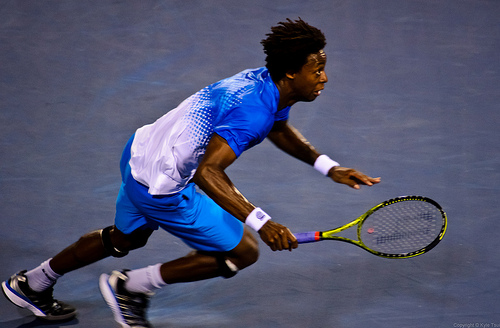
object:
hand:
[257, 220, 297, 251]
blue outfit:
[127, 66, 290, 192]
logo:
[376, 213, 430, 243]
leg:
[125, 184, 259, 281]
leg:
[50, 184, 154, 274]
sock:
[123, 262, 169, 291]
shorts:
[115, 134, 242, 251]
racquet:
[289, 195, 448, 256]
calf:
[50, 229, 129, 272]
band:
[215, 258, 237, 280]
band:
[99, 225, 126, 256]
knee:
[204, 227, 259, 271]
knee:
[111, 216, 147, 251]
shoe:
[1, 269, 77, 321]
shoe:
[97, 267, 154, 327]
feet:
[2, 269, 76, 320]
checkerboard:
[180, 66, 279, 158]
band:
[245, 207, 272, 232]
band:
[313, 154, 340, 176]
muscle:
[196, 165, 254, 221]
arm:
[192, 104, 273, 220]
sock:
[25, 257, 61, 290]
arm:
[267, 107, 320, 165]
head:
[259, 17, 329, 102]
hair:
[259, 17, 325, 81]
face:
[296, 49, 328, 101]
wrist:
[245, 207, 270, 233]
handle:
[290, 231, 320, 243]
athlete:
[0, 15, 382, 325]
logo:
[256, 211, 265, 221]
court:
[0, 0, 498, 327]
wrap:
[286, 231, 324, 243]